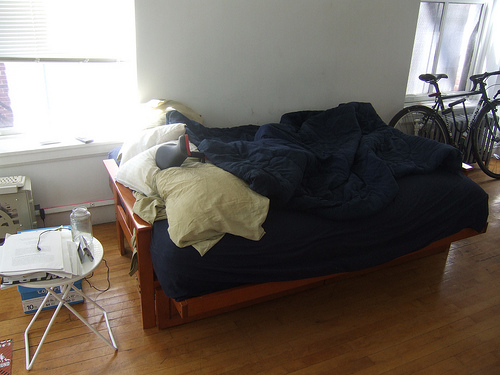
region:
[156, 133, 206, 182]
a bike seat on a bed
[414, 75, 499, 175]
bike leaning against a wall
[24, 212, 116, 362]
a small table with a bunch of papers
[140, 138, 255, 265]
bed pillows on the bed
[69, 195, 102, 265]
a glass jar on the table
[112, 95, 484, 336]
a bed with a trundle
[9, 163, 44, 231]
a computer tower on the floor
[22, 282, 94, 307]
a card board box on the floor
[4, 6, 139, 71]
a white blind at the window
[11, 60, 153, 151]
sunlight coming through the window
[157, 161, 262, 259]
big pillow on a bed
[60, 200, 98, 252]
white jar on a table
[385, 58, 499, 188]
black bike parked inside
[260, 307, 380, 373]
wooden slats on the ground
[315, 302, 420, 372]
wooden flooring in a bedroom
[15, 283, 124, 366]
white metal bottom on a tray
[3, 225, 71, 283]
stack of paper on a table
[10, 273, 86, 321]
blue and white cardboard box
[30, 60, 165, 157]
sunlight shining through the window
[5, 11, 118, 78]
white blinds covering a window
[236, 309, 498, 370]
wooden floor of a bedroom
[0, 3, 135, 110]
window in a wall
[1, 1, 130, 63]
window blinds closed, but pulled half way up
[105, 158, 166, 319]
bed with a wooden frame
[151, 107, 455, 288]
queen sized mattress with navy blue sheets and comforter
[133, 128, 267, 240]
two white pillow cases and pillows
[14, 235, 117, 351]
small fold out table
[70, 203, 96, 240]
mason jar to drink from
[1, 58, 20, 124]
brick wall from neighboring building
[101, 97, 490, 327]
Futon bed beside the wall.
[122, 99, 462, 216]
black comforter on the bed.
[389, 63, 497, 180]
Bicycle beside the window.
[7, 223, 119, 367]
White table beside the bed.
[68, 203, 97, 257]
Glass jar on the table.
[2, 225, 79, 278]
Papers on the table.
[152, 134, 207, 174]
bicycle seat on the pillow.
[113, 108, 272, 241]
Pillows on the bed.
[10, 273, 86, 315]
box on the floor.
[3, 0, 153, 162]
window in the wall.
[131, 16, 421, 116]
white wall in the room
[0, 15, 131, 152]
window has sunlight coming through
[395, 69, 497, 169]
a bicycle left of bed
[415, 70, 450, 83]
the seat of bike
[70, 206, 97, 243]
a clear jar to right of bed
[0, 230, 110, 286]
white tabletop with papers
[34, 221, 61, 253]
a cord on the papers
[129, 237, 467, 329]
bed and wooden base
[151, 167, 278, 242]
pillow is yellow on bed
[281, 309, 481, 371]
the floors are wooden